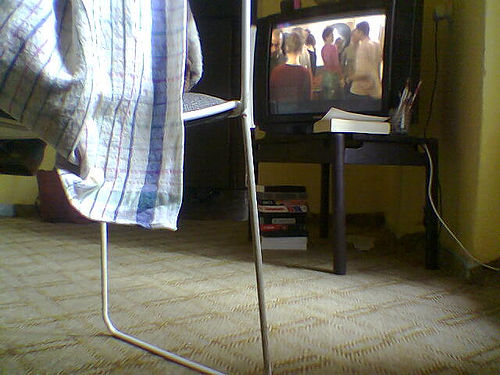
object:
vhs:
[252, 184, 309, 255]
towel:
[5, 0, 201, 231]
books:
[258, 224, 309, 234]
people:
[320, 27, 343, 103]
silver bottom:
[99, 123, 274, 373]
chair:
[0, 0, 272, 374]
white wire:
[420, 145, 494, 280]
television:
[255, 7, 427, 136]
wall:
[422, 2, 497, 267]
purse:
[31, 167, 87, 225]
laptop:
[36, 169, 95, 226]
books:
[254, 236, 307, 252]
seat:
[164, 91, 242, 125]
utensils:
[390, 76, 424, 134]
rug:
[293, 289, 467, 370]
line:
[282, 317, 318, 335]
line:
[346, 335, 362, 350]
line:
[279, 352, 308, 373]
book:
[313, 105, 392, 135]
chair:
[318, 124, 447, 278]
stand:
[243, 124, 443, 276]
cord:
[415, 136, 498, 276]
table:
[216, 122, 446, 277]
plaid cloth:
[1, 0, 203, 230]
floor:
[1, 216, 499, 373]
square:
[291, 318, 374, 351]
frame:
[96, 3, 283, 363]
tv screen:
[267, 10, 382, 113]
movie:
[255, 201, 311, 214]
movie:
[256, 223, 304, 233]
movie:
[254, 192, 307, 199]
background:
[13, 14, 473, 255]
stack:
[254, 177, 313, 252]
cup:
[391, 110, 412, 134]